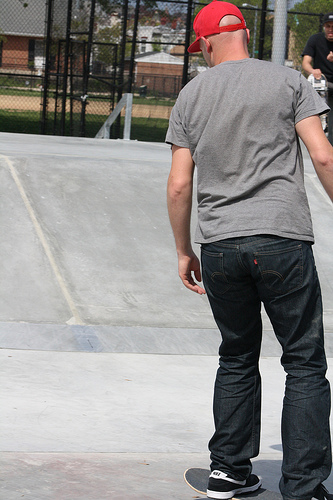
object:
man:
[163, 0, 331, 499]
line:
[0, 152, 85, 324]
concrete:
[0, 133, 330, 498]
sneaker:
[205, 470, 262, 499]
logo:
[212, 471, 222, 479]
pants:
[196, 234, 332, 498]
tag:
[253, 258, 260, 264]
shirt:
[164, 59, 330, 245]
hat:
[187, 0, 248, 59]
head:
[193, 2, 249, 63]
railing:
[94, 91, 134, 139]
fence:
[0, 0, 332, 133]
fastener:
[218, 24, 247, 32]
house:
[1, 1, 180, 93]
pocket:
[254, 248, 301, 291]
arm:
[166, 94, 205, 296]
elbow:
[167, 175, 192, 206]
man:
[301, 5, 332, 140]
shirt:
[302, 33, 333, 81]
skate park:
[0, 0, 332, 500]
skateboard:
[183, 467, 264, 500]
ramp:
[3, 156, 330, 353]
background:
[0, 0, 332, 139]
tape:
[209, 467, 257, 487]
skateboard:
[308, 73, 329, 138]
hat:
[322, 15, 332, 25]